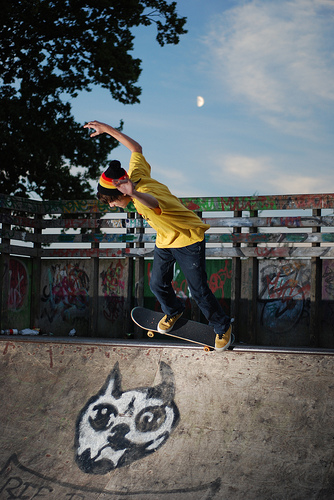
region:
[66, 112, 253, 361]
Boy in yellow shirt.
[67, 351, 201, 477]
Black and white painted dog.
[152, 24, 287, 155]
Half moon in the sky.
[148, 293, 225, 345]
Bright yellow tennis shoes on boy.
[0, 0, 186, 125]
Tree outline in the sky.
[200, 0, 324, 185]
Blue sky with clouds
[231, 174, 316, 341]
Spray painted fence with the number 5 on it.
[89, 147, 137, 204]
Boy in black yellow and orange hat.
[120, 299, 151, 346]
Skateboard with yellow wheels.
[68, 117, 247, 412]
Boy with arms high doing skateboarding moves.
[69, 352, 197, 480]
black and white dog is memorialized on a ramp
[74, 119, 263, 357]
skateboarder reaches top of platform and begins decent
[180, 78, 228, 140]
half of the moon is in a blue sky with clouds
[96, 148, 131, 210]
skateboarder wears kit hat with stripes and pompom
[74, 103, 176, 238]
skateboarder's arms are over his head for balance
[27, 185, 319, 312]
graffiti is sprayed on fence behind top of ramp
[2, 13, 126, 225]
tall tree has branches near the corner of skate ramp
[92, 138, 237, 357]
skateboarder wears yellow shirt and shoes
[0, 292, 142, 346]
trash is strewn along the back of platform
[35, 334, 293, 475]
ramp has scraped paint and black marks from use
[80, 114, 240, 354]
boy on skateboard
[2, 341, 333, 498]
skating surface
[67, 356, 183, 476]
black and white image of animal on skating surface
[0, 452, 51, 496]
black writing on skating surface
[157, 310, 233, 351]
boy wearing yellow shoes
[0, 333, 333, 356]
metal band on top of skating surface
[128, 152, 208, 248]
boy wearing yellow shirt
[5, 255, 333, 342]
graffiti on wall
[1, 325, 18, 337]
empty drink can on its side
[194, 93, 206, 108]
moon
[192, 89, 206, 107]
Half moon in the sky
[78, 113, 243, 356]
Young man in a skateboard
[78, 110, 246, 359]
Boy wearing yellow tennis shoes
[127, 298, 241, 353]
Skateboard with yellow wheels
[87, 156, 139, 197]
Cap on head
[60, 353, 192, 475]
Graffiti on skateboard track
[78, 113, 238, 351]
Boy wearing blue jeans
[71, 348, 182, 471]
White and black graffiti on skateboard track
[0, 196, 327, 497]
Skateboard track of concrete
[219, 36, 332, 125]
Clouds in the sky